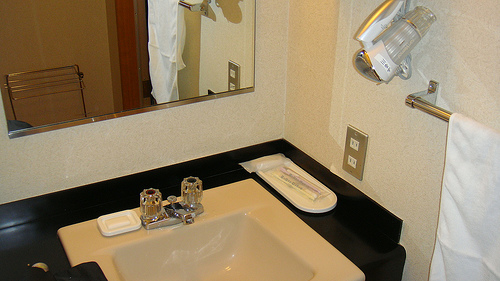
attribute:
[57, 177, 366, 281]
sink — off white, square, shiny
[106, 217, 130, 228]
soap — white, small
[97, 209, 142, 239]
soap dish — white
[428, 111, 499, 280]
towel — white, hanging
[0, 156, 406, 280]
counter — black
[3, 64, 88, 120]
luggage rack — metal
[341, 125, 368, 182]
outlet — silver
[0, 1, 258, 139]
mirror — hanging, wide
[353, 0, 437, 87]
hairdryer — hanging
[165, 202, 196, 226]
faucet — silver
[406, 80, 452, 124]
rack — silver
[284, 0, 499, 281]
wall — cream